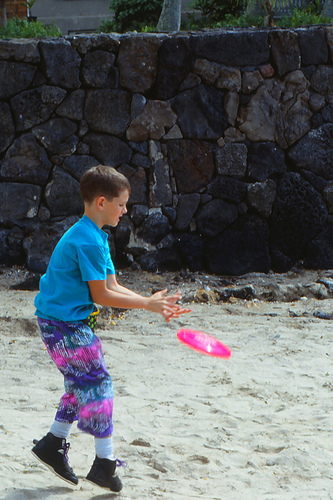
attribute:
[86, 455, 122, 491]
shoe — tennis, black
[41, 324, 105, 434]
pants — multi colored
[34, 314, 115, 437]
pants — flamboyant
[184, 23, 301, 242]
wall — rock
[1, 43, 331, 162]
wall — tall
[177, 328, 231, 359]
frisbee — pink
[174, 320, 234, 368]
frisbee — pink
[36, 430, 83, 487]
shoe — black, tennis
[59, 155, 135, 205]
hair cut — short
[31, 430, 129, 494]
shoes — black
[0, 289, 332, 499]
sand — white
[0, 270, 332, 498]
ground — white, sand covered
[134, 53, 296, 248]
structure — rock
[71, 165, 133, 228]
head — boy